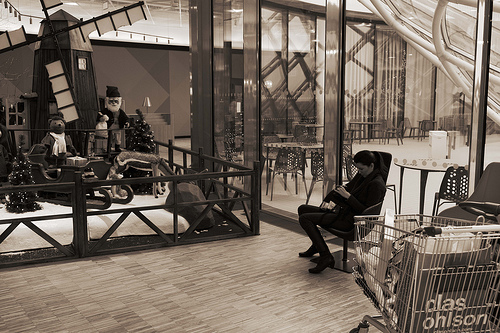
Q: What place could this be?
A: It is a display.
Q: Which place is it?
A: It is a display.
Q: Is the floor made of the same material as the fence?
A: Yes, both the floor and the fence are made of wood.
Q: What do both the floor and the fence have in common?
A: The material, both the floor and the fence are wooden.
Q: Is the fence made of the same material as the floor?
A: Yes, both the fence and the floor are made of wood.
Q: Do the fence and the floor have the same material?
A: Yes, both the fence and the floor are made of wood.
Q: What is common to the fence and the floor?
A: The material, both the fence and the floor are wooden.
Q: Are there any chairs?
A: Yes, there is a chair.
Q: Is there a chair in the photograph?
A: Yes, there is a chair.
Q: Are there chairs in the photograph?
A: Yes, there is a chair.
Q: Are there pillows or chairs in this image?
A: Yes, there is a chair.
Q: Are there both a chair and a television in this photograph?
A: No, there is a chair but no televisions.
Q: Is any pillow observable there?
A: No, there are no pillows.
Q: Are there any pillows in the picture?
A: No, there are no pillows.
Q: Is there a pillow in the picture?
A: No, there are no pillows.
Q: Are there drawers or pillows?
A: No, there are no pillows or drawers.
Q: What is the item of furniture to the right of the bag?
A: The piece of furniture is a chair.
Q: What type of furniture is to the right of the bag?
A: The piece of furniture is a chair.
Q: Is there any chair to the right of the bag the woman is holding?
A: Yes, there is a chair to the right of the bag.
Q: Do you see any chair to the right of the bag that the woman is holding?
A: Yes, there is a chair to the right of the bag.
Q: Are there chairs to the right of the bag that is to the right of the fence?
A: Yes, there is a chair to the right of the bag.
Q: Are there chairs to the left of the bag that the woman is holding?
A: No, the chair is to the right of the bag.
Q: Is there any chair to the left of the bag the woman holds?
A: No, the chair is to the right of the bag.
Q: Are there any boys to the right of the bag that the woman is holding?
A: No, there is a chair to the right of the bag.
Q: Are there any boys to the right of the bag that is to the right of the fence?
A: No, there is a chair to the right of the bag.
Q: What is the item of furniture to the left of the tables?
A: The piece of furniture is a chair.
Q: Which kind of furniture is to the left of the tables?
A: The piece of furniture is a chair.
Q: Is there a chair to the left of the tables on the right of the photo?
A: Yes, there is a chair to the left of the tables.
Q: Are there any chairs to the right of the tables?
A: No, the chair is to the left of the tables.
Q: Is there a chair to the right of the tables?
A: No, the chair is to the left of the tables.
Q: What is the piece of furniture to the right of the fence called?
A: The piece of furniture is a chair.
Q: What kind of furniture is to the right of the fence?
A: The piece of furniture is a chair.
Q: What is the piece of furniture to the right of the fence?
A: The piece of furniture is a chair.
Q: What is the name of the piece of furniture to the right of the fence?
A: The piece of furniture is a chair.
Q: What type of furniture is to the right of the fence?
A: The piece of furniture is a chair.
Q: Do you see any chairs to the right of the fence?
A: Yes, there is a chair to the right of the fence.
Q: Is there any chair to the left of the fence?
A: No, the chair is to the right of the fence.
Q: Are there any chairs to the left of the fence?
A: No, the chair is to the right of the fence.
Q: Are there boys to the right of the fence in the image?
A: No, there is a chair to the right of the fence.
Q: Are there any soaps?
A: No, there are no soaps.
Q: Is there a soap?
A: No, there are no soaps.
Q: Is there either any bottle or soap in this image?
A: No, there are no soaps or bottles.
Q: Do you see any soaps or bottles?
A: No, there are no soaps or bottles.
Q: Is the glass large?
A: Yes, the glass is large.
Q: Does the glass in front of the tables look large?
A: Yes, the glass is large.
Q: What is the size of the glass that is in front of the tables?
A: The glass is large.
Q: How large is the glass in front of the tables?
A: The glass is large.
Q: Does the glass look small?
A: No, the glass is large.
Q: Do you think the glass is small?
A: No, the glass is large.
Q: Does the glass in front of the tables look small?
A: No, the glass is large.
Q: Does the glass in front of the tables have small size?
A: No, the glass is large.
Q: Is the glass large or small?
A: The glass is large.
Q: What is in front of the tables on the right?
A: The glass is in front of the tables.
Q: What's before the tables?
A: The glass is in front of the tables.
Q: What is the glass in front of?
A: The glass is in front of the tables.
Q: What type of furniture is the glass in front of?
A: The glass is in front of the tables.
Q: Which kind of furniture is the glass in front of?
A: The glass is in front of the tables.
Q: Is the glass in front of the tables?
A: Yes, the glass is in front of the tables.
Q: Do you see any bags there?
A: Yes, there is a bag.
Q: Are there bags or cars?
A: Yes, there is a bag.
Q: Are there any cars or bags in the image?
A: Yes, there is a bag.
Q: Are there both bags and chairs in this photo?
A: Yes, there are both a bag and a chair.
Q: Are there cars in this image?
A: No, there are no cars.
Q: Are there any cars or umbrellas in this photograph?
A: No, there are no cars or umbrellas.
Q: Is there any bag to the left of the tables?
A: Yes, there is a bag to the left of the tables.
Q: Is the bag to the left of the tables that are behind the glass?
A: Yes, the bag is to the left of the tables.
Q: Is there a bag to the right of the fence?
A: Yes, there is a bag to the right of the fence.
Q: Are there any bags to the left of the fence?
A: No, the bag is to the right of the fence.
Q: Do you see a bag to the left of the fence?
A: No, the bag is to the right of the fence.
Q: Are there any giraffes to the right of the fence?
A: No, there is a bag to the right of the fence.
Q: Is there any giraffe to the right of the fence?
A: No, there is a bag to the right of the fence.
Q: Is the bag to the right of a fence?
A: Yes, the bag is to the right of a fence.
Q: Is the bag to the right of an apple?
A: No, the bag is to the right of a fence.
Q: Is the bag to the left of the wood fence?
A: No, the bag is to the right of the fence.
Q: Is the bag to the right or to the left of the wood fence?
A: The bag is to the right of the fence.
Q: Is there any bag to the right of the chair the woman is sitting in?
A: No, the bag is to the left of the chair.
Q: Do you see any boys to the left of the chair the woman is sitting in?
A: No, there is a bag to the left of the chair.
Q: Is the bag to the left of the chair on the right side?
A: Yes, the bag is to the left of the chair.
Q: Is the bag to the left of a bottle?
A: No, the bag is to the left of the chair.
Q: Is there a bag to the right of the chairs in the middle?
A: Yes, there is a bag to the right of the chairs.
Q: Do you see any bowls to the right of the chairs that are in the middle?
A: No, there is a bag to the right of the chairs.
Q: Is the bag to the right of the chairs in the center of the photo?
A: Yes, the bag is to the right of the chairs.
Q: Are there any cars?
A: No, there are no cars.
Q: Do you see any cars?
A: No, there are no cars.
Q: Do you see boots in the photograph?
A: Yes, there are boots.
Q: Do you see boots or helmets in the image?
A: Yes, there are boots.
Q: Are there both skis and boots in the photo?
A: No, there are boots but no skis.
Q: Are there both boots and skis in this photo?
A: No, there are boots but no skis.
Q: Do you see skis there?
A: No, there are no skis.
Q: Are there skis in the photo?
A: No, there are no skis.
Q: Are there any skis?
A: No, there are no skis.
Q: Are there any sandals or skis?
A: No, there are no skis or sandals.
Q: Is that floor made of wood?
A: Yes, the floor is made of wood.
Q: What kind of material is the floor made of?
A: The floor is made of wood.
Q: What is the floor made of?
A: The floor is made of wood.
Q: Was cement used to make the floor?
A: No, the floor is made of wood.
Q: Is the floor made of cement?
A: No, the floor is made of wood.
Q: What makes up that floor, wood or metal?
A: The floor is made of wood.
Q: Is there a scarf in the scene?
A: Yes, there is a scarf.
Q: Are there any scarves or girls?
A: Yes, there is a scarf.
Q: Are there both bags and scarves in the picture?
A: Yes, there are both a scarf and a bag.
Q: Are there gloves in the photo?
A: No, there are no gloves.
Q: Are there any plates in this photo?
A: No, there are no plates.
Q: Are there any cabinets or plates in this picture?
A: No, there are no plates or cabinets.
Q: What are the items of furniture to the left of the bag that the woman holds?
A: The pieces of furniture are chairs.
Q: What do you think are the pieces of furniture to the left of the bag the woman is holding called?
A: The pieces of furniture are chairs.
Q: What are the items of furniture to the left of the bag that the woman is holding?
A: The pieces of furniture are chairs.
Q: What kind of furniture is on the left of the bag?
A: The pieces of furniture are chairs.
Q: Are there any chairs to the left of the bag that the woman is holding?
A: Yes, there are chairs to the left of the bag.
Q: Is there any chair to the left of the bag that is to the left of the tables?
A: Yes, there are chairs to the left of the bag.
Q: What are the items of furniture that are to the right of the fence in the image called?
A: The pieces of furniture are chairs.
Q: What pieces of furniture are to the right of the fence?
A: The pieces of furniture are chairs.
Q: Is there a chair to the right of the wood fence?
A: Yes, there are chairs to the right of the fence.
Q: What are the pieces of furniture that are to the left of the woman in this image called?
A: The pieces of furniture are chairs.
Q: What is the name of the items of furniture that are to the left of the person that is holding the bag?
A: The pieces of furniture are chairs.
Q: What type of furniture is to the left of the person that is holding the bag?
A: The pieces of furniture are chairs.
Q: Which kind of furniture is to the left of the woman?
A: The pieces of furniture are chairs.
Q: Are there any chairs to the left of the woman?
A: Yes, there are chairs to the left of the woman.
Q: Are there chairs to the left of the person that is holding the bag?
A: Yes, there are chairs to the left of the woman.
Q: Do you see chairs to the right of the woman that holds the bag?
A: No, the chairs are to the left of the woman.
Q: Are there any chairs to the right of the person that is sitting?
A: No, the chairs are to the left of the woman.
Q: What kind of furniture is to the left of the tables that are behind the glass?
A: The pieces of furniture are chairs.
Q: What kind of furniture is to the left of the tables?
A: The pieces of furniture are chairs.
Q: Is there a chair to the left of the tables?
A: Yes, there are chairs to the left of the tables.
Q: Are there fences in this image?
A: Yes, there is a fence.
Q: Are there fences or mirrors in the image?
A: Yes, there is a fence.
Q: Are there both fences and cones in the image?
A: No, there is a fence but no cones.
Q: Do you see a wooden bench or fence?
A: Yes, there is a wood fence.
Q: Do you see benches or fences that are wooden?
A: Yes, the fence is wooden.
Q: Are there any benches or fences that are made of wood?
A: Yes, the fence is made of wood.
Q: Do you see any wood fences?
A: Yes, there is a fence that is made of wood.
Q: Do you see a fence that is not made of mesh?
A: Yes, there is a fence that is made of wood.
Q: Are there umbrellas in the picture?
A: No, there are no umbrellas.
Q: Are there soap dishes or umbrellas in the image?
A: No, there are no umbrellas or soap dishes.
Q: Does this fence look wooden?
A: Yes, the fence is wooden.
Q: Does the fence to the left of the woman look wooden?
A: Yes, the fence is wooden.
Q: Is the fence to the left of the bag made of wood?
A: Yes, the fence is made of wood.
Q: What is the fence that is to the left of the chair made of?
A: The fence is made of wood.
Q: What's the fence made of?
A: The fence is made of wood.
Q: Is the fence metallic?
A: No, the fence is wooden.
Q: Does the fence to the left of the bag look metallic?
A: No, the fence is wooden.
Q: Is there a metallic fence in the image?
A: No, there is a fence but it is wooden.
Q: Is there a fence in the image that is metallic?
A: No, there is a fence but it is wooden.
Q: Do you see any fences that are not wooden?
A: No, there is a fence but it is wooden.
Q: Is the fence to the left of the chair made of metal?
A: No, the fence is made of wood.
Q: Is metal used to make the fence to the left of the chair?
A: No, the fence is made of wood.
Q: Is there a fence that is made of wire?
A: No, there is a fence but it is made of wood.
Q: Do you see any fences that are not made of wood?
A: No, there is a fence but it is made of wood.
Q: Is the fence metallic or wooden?
A: The fence is wooden.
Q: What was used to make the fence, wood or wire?
A: The fence is made of wood.